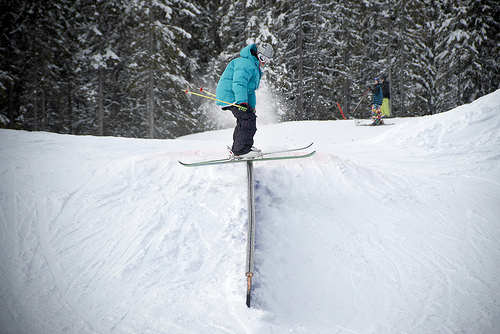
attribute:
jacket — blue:
[205, 46, 261, 107]